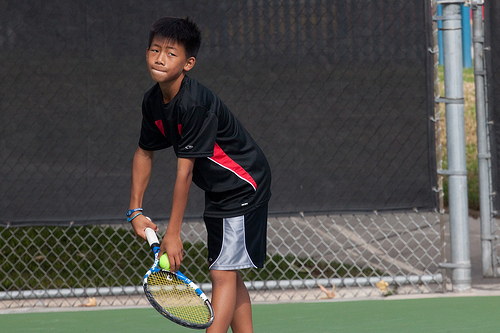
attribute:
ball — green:
[155, 250, 175, 268]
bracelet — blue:
[123, 208, 143, 215]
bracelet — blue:
[125, 211, 142, 223]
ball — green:
[116, 234, 236, 283]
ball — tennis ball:
[155, 251, 170, 268]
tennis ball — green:
[159, 254, 169, 270]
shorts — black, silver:
[204, 200, 268, 269]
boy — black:
[112, 14, 302, 273]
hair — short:
[148, 16, 205, 46]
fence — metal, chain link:
[3, 2, 498, 316]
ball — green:
[157, 249, 175, 274]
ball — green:
[153, 248, 185, 275]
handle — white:
[124, 205, 169, 245]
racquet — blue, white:
[138, 217, 216, 327]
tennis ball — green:
[154, 251, 172, 278]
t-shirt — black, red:
[139, 89, 279, 217]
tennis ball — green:
[156, 250, 173, 270]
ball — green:
[144, 243, 185, 265]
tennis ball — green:
[134, 231, 204, 277]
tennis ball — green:
[159, 253, 168, 272]